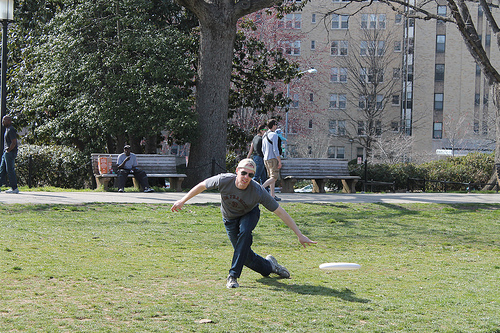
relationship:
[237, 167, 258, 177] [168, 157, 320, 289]
sunglasses on person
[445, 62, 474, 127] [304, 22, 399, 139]
wall on building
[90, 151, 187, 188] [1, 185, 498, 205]
bench on road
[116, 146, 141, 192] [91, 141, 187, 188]
man on bench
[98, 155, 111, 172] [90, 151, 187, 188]
bag on bench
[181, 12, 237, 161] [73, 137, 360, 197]
tree between benches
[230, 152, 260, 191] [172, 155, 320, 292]
head of person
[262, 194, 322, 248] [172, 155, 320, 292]
arm of person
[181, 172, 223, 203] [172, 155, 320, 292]
arm of person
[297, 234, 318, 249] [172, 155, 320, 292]
hand of person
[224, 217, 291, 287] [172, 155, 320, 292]
leg of person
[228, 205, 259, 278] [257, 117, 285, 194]
leg of person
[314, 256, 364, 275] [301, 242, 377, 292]
frisbee in air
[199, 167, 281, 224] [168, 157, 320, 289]
shirt on person